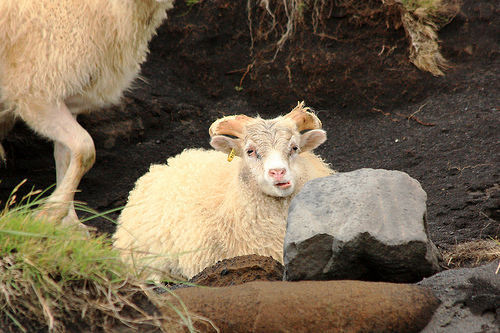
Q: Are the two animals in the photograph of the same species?
A: Yes, all the animals are goats.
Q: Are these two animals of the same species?
A: Yes, all the animals are goats.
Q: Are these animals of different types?
A: No, all the animals are goats.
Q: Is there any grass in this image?
A: Yes, there is grass.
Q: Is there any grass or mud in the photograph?
A: Yes, there is grass.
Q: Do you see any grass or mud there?
A: Yes, there is grass.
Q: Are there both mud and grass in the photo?
A: No, there is grass but no mud.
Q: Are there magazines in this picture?
A: No, there are no magazines.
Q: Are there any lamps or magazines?
A: No, there are no magazines or lamps.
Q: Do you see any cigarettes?
A: No, there are no cigarettes.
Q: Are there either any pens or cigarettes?
A: No, there are no cigarettes or pens.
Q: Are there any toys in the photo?
A: No, there are no toys.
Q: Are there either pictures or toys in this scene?
A: No, there are no toys or pictures.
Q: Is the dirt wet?
A: Yes, the dirt is wet.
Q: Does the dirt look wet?
A: Yes, the dirt is wet.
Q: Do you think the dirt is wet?
A: Yes, the dirt is wet.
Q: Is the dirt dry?
A: No, the dirt is wet.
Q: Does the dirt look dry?
A: No, the dirt is wet.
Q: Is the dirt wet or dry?
A: The dirt is wet.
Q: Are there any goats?
A: Yes, there is a goat.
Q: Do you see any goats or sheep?
A: Yes, there is a goat.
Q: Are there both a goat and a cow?
A: No, there is a goat but no cows.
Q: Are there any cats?
A: No, there are no cats.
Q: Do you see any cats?
A: No, there are no cats.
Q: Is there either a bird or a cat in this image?
A: No, there are no cats or birds.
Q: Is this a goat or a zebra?
A: This is a goat.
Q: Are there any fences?
A: No, there are no fences.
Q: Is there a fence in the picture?
A: No, there are no fences.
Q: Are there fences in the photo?
A: No, there are no fences.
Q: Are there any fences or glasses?
A: No, there are no fences or glasses.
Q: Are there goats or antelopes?
A: Yes, there is a goat.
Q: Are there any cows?
A: No, there are no cows.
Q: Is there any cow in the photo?
A: No, there are no cows.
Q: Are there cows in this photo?
A: No, there are no cows.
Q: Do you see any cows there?
A: No, there are no cows.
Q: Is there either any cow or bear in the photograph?
A: No, there are no cows or bears.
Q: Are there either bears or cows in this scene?
A: No, there are no cows or bears.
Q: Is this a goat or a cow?
A: This is a goat.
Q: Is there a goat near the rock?
A: Yes, there is a goat near the rock.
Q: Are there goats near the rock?
A: Yes, there is a goat near the rock.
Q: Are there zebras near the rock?
A: No, there is a goat near the rock.